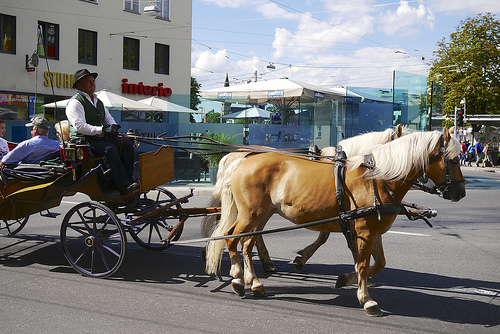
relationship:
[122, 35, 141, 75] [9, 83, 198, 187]
window on building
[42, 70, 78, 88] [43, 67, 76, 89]
sign with name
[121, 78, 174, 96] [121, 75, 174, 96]
name with name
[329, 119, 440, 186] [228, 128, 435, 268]
mane on horse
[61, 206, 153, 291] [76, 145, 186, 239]
spoke on wheel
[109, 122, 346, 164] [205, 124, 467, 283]
reins on a horse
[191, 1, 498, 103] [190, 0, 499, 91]
clouds in sky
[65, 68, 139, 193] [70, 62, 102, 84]
driver wearing hat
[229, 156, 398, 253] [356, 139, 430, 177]
horse has mane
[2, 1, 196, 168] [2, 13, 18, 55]
building has window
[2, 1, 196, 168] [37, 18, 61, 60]
building has window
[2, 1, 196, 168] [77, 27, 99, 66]
building has window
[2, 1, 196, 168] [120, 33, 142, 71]
building has window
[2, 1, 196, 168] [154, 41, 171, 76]
building has window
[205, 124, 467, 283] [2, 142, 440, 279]
horse pulling carriage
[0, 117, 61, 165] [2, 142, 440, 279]
passengers in carriage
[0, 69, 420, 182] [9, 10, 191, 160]
walls around eatery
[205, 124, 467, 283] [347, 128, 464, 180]
horse has mane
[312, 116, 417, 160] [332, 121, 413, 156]
horse has mane